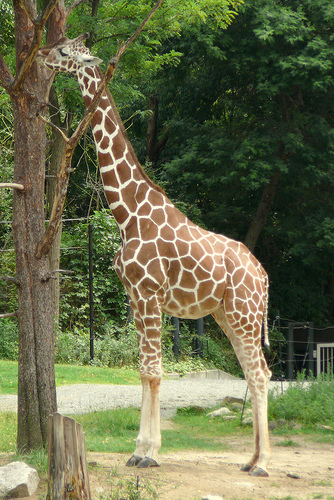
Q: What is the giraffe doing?
A: Eating from the tree.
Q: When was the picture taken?
A: During the day.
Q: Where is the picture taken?
A: At the zoo.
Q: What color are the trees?
A: Green.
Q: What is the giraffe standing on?
A: The ground.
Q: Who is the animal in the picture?
A: A giraffe.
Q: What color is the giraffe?
A: Brown and white.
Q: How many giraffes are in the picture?
A: One.